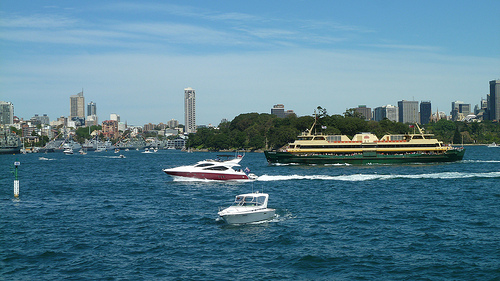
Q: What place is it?
A: It is a city.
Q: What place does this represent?
A: It represents the city.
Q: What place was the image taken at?
A: It was taken at the city.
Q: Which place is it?
A: It is a city.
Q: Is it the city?
A: Yes, it is the city.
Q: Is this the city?
A: Yes, it is the city.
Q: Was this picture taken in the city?
A: Yes, it was taken in the city.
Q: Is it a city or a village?
A: It is a city.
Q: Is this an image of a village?
A: No, the picture is showing a city.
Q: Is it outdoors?
A: Yes, it is outdoors.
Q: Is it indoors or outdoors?
A: It is outdoors.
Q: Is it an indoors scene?
A: No, it is outdoors.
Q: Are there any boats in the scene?
A: Yes, there is a boat.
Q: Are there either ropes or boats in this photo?
A: Yes, there is a boat.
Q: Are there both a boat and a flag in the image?
A: No, there is a boat but no flags.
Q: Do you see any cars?
A: No, there are no cars.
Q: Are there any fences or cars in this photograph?
A: No, there are no cars or fences.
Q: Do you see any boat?
A: Yes, there is a boat.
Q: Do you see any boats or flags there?
A: Yes, there is a boat.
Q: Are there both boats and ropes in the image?
A: No, there is a boat but no ropes.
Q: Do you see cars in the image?
A: No, there are no cars.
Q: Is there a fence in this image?
A: No, there are no fences.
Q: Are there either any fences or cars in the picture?
A: No, there are no fences or cars.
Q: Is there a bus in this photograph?
A: No, there are no buses.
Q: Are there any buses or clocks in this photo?
A: No, there are no buses or clocks.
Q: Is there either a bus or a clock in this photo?
A: No, there are no buses or clocks.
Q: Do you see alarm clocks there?
A: No, there are no alarm clocks.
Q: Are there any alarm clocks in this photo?
A: No, there are no alarm clocks.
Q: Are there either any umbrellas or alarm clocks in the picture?
A: No, there are no alarm clocks or umbrellas.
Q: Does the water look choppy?
A: Yes, the water is choppy.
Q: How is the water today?
A: The water is choppy.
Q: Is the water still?
A: No, the water is choppy.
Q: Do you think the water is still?
A: No, the water is choppy.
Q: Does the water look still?
A: No, the water is choppy.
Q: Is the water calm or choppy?
A: The water is choppy.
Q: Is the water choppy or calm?
A: The water is choppy.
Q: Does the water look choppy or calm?
A: The water is choppy.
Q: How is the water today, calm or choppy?
A: The water is choppy.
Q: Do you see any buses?
A: No, there are no buses.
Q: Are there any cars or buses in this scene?
A: No, there are no buses or cars.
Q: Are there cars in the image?
A: No, there are no cars.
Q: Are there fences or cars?
A: No, there are no cars or fences.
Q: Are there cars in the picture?
A: No, there are no cars.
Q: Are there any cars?
A: No, there are no cars.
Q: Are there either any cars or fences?
A: No, there are no cars or fences.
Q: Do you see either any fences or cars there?
A: No, there are no cars or fences.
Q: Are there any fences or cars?
A: No, there are no cars or fences.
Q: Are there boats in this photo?
A: Yes, there is a boat.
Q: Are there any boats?
A: Yes, there is a boat.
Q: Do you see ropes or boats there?
A: Yes, there is a boat.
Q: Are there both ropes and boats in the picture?
A: No, there is a boat but no ropes.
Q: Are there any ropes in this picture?
A: No, there are no ropes.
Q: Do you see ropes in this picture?
A: No, there are no ropes.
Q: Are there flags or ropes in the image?
A: No, there are no ropes or flags.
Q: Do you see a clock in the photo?
A: No, there are no clocks.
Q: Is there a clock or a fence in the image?
A: No, there are no clocks or fences.